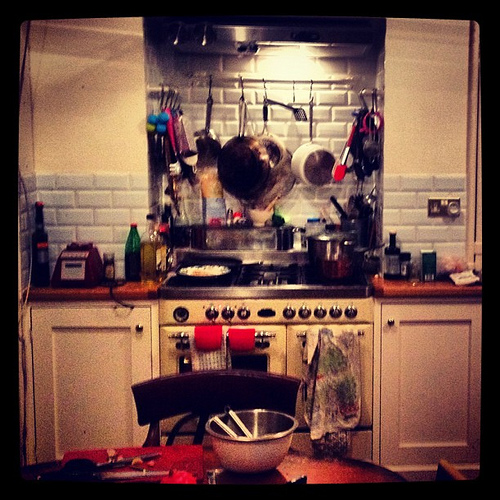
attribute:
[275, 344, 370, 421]
towel — hanging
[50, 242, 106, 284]
bottom — electircal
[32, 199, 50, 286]
bottle — tall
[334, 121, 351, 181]
spatula — red, hanging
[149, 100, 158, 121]
item — hanging, blue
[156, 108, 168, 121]
item — hanging, blue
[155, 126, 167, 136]
item — hanging, blue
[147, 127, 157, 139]
item — hanging, green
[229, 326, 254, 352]
towel — red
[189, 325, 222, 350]
towel — red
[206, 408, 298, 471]
mixing bowl — silver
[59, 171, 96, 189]
tile — rectangle, white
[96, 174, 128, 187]
tile — rectangle, white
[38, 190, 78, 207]
tile — rectangle, white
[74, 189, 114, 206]
tile — rectangle, white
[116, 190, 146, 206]
tile — rectangle, white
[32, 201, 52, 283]
bottle — tall, dark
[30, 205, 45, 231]
neck — tall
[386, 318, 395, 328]
handle — silver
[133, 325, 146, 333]
handle — silver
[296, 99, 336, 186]
saucepan — white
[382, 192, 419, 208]
subway tile — white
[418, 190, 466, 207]
subway tile — white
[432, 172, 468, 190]
subway tile — white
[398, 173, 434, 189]
subway tile — white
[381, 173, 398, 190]
subway tile — white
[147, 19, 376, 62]
vent hood — silver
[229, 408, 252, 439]
utensil — silver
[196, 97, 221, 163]
pot — hanging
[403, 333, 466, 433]
paint — white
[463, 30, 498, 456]
frame — black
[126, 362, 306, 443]
chair — wooden